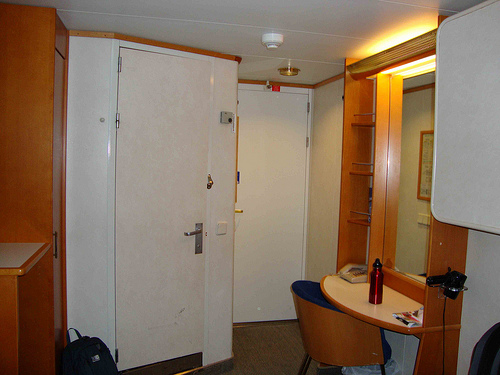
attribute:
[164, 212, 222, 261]
handle — silver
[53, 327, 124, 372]
backpack — blue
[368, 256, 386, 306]
bottle — red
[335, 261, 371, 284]
phone — beige, landline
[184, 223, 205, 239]
handle — silver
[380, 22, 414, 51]
light — on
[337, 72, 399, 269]
shelf — wooden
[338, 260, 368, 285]
phone — dark, beige, outdated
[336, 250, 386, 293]
phone — white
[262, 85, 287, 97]
sticker — red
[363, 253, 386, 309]
bottle — red, metallic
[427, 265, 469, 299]
hairdryer — black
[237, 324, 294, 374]
floor — carpeted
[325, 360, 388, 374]
can — garbage can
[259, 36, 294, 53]
fire alarm — white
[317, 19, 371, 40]
ceiling — white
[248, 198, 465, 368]
desk — lightly colored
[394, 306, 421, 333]
book — open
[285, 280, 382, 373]
chair — wooden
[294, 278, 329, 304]
cushion — blue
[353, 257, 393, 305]
bottle — water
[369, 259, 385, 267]
top — black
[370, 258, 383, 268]
lid — black